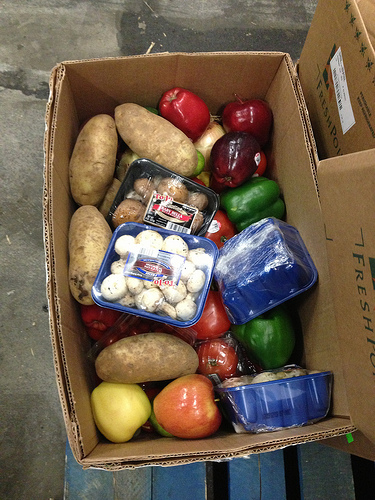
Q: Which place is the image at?
A: It is at the sidewalk.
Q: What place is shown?
A: It is a sidewalk.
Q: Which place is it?
A: It is a sidewalk.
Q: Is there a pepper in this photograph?
A: Yes, there is a pepper.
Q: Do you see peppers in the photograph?
A: Yes, there is a pepper.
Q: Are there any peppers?
A: Yes, there is a pepper.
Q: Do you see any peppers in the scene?
A: Yes, there is a pepper.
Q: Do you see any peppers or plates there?
A: Yes, there is a pepper.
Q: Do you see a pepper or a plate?
A: Yes, there is a pepper.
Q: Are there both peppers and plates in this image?
A: No, there is a pepper but no plates.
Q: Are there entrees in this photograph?
A: No, there are no entrees.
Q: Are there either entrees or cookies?
A: No, there are no entrees or cookies.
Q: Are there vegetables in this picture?
A: Yes, there are vegetables.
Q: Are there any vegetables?
A: Yes, there are vegetables.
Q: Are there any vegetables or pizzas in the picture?
A: Yes, there are vegetables.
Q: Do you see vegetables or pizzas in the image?
A: Yes, there are vegetables.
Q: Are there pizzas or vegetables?
A: Yes, there are vegetables.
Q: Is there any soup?
A: No, there is no soup.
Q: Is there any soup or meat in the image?
A: No, there are no soup or meat.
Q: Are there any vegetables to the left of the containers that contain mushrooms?
A: Yes, there are vegetables to the left of the containers.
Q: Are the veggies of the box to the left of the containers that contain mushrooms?
A: Yes, the vegetables are to the left of the containers.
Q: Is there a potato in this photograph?
A: Yes, there are potatoes.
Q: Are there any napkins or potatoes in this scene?
A: Yes, there are potatoes.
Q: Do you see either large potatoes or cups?
A: Yes, there are large potatoes.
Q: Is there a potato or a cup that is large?
A: Yes, the potatoes are large.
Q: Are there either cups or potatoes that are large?
A: Yes, the potatoes are large.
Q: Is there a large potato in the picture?
A: Yes, there are large potatoes.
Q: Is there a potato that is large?
A: Yes, there are potatoes that are large.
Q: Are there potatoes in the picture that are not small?
A: Yes, there are large potatoes.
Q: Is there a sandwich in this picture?
A: No, there are no sandwiches.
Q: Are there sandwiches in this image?
A: No, there are no sandwiches.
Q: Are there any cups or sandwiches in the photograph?
A: No, there are no sandwiches or cups.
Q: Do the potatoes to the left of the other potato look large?
A: Yes, the potatoes are large.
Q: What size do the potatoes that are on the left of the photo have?
A: The potatoes have large size.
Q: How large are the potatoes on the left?
A: The potatoes are large.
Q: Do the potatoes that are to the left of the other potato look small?
A: No, the potatoes are large.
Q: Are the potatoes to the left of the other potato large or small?
A: The potatoes are large.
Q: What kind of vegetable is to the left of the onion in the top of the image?
A: The vegetables are potatoes.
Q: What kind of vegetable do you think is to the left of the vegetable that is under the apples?
A: The vegetables are potatoes.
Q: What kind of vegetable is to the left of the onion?
A: The vegetables are potatoes.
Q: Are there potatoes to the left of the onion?
A: Yes, there are potatoes to the left of the onion.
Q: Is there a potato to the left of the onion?
A: Yes, there are potatoes to the left of the onion.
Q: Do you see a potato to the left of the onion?
A: Yes, there are potatoes to the left of the onion.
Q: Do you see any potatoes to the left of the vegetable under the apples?
A: Yes, there are potatoes to the left of the onion.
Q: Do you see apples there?
A: Yes, there is an apple.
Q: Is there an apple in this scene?
A: Yes, there is an apple.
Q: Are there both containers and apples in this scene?
A: Yes, there are both an apple and a container.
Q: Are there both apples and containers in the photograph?
A: Yes, there are both an apple and a container.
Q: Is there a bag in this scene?
A: No, there are no bags.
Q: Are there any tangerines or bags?
A: No, there are no bags or tangerines.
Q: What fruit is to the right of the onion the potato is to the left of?
A: The fruit is an apple.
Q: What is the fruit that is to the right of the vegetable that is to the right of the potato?
A: The fruit is an apple.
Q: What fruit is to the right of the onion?
A: The fruit is an apple.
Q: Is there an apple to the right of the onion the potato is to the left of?
A: Yes, there is an apple to the right of the onion.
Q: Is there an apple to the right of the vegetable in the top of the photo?
A: Yes, there is an apple to the right of the onion.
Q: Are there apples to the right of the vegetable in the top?
A: Yes, there is an apple to the right of the onion.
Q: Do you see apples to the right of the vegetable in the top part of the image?
A: Yes, there is an apple to the right of the onion.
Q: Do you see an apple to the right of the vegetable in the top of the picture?
A: Yes, there is an apple to the right of the onion.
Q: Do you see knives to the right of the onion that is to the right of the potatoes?
A: No, there is an apple to the right of the onion.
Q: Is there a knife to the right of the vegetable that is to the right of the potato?
A: No, there is an apple to the right of the onion.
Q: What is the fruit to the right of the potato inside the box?
A: The fruit is an apple.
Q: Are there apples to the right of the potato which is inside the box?
A: Yes, there is an apple to the right of the potato.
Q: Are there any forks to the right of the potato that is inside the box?
A: No, there is an apple to the right of the potato.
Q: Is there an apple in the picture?
A: Yes, there are apples.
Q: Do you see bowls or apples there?
A: Yes, there are apples.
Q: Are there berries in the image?
A: No, there are no berries.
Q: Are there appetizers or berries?
A: No, there are no berries or appetizers.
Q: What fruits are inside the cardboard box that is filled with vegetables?
A: The fruits are apples.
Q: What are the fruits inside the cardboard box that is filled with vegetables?
A: The fruits are apples.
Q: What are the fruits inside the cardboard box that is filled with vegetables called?
A: The fruits are apples.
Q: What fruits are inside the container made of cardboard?
A: The fruits are apples.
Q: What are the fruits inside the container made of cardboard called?
A: The fruits are apples.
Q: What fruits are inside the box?
A: The fruits are apples.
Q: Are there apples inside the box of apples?
A: Yes, there are apples inside the box.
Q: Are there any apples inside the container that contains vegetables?
A: Yes, there are apples inside the box.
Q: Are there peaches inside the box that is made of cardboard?
A: No, there are apples inside the box.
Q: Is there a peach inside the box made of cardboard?
A: No, there are apples inside the box.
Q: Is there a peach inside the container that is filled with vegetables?
A: No, there are apples inside the box.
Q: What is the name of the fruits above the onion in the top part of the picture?
A: The fruits are apples.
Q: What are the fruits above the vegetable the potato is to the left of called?
A: The fruits are apples.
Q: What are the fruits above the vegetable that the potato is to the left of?
A: The fruits are apples.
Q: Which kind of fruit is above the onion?
A: The fruits are apples.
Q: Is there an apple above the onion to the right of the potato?
A: Yes, there are apples above the onion.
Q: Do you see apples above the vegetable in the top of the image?
A: Yes, there are apples above the onion.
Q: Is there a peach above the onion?
A: No, there are apples above the onion.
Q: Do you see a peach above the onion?
A: No, there are apples above the onion.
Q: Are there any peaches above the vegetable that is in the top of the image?
A: No, there are apples above the onion.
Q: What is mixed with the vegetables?
A: The apples are mixed with the vegetables.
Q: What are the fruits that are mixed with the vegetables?
A: The fruits are apples.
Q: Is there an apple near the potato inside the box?
A: Yes, there are apples near the potato.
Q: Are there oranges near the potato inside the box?
A: No, there are apples near the potato.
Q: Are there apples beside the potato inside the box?
A: Yes, there are apples beside the potato.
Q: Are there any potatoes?
A: Yes, there is a potato.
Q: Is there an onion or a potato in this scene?
A: Yes, there is a potato.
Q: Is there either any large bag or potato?
A: Yes, there is a large potato.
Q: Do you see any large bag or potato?
A: Yes, there is a large potato.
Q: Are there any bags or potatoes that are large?
A: Yes, the potato is large.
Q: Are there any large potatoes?
A: Yes, there is a large potato.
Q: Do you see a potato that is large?
A: Yes, there is a potato that is large.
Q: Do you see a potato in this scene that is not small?
A: Yes, there is a large potato.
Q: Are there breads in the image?
A: No, there are no breads.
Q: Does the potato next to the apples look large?
A: Yes, the potato is large.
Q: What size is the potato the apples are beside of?
A: The potato is large.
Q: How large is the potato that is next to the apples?
A: The potato is large.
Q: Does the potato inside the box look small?
A: No, the potato is large.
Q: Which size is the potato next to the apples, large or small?
A: The potato is large.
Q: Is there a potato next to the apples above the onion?
A: Yes, there is a potato next to the apples.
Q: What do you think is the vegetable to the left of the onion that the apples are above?
A: The vegetable is a potato.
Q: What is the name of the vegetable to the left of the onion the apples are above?
A: The vegetable is a potato.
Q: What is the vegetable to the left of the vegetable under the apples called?
A: The vegetable is a potato.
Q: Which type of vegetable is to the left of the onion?
A: The vegetable is a potato.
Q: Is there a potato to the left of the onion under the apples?
A: Yes, there is a potato to the left of the onion.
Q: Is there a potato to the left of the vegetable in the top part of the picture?
A: Yes, there is a potato to the left of the onion.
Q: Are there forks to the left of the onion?
A: No, there is a potato to the left of the onion.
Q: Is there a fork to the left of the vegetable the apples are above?
A: No, there is a potato to the left of the onion.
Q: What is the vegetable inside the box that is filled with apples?
A: The vegetable is a potato.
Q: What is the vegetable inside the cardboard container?
A: The vegetable is a potato.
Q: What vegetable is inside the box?
A: The vegetable is a potato.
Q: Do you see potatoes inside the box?
A: Yes, there is a potato inside the box.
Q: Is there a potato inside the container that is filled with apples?
A: Yes, there is a potato inside the box.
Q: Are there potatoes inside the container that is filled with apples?
A: Yes, there is a potato inside the box.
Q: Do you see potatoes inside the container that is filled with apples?
A: Yes, there is a potato inside the box.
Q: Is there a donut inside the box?
A: No, there is a potato inside the box.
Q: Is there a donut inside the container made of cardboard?
A: No, there is a potato inside the box.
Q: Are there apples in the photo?
A: Yes, there is an apple.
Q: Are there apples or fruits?
A: Yes, there is an apple.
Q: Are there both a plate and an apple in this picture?
A: No, there is an apple but no plates.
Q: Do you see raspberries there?
A: No, there are no raspberries.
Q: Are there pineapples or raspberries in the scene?
A: No, there are no raspberries or pineapples.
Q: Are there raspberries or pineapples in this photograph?
A: No, there are no raspberries or pineapples.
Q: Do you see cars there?
A: No, there are no cars.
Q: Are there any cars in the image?
A: No, there are no cars.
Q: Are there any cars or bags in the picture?
A: No, there are no cars or bags.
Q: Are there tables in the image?
A: Yes, there is a table.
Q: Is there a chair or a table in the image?
A: Yes, there is a table.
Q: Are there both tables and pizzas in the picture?
A: No, there is a table but no pizzas.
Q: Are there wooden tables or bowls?
A: Yes, there is a wood table.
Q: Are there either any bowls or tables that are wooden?
A: Yes, the table is wooden.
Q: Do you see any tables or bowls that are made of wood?
A: Yes, the table is made of wood.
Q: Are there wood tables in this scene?
A: Yes, there is a wood table.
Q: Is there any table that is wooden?
A: Yes, there is a table that is wooden.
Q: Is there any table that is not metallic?
A: Yes, there is a wooden table.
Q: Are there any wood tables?
A: Yes, there is a table that is made of wood.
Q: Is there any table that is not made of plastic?
A: Yes, there is a table that is made of wood.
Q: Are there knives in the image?
A: No, there are no knives.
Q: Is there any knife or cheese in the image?
A: No, there are no knives or cheese.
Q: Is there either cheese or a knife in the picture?
A: No, there are no knives or cheese.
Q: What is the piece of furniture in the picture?
A: The piece of furniture is a table.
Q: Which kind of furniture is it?
A: The piece of furniture is a table.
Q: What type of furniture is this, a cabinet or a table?
A: This is a table.